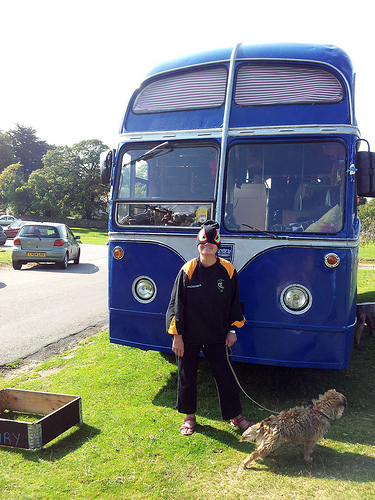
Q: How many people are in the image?
A: One.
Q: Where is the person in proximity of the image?
A: Center.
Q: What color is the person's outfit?
A: Black and yellow.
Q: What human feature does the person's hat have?
A: Eyes.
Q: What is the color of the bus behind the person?
A: Blue.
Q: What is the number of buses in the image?
A: One.